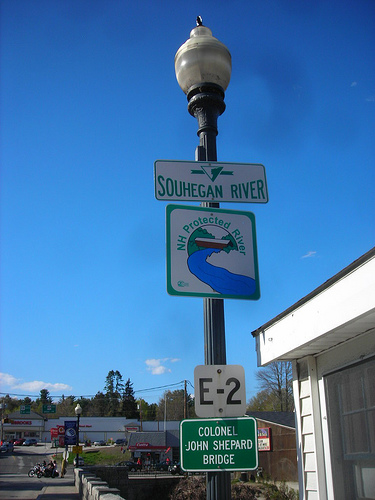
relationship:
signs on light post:
[151, 154, 270, 301] [170, 12, 236, 498]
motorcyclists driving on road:
[27, 460, 59, 478] [7, 452, 60, 490]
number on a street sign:
[224, 375, 243, 408] [193, 363, 246, 417]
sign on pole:
[157, 196, 295, 331] [130, 11, 333, 492]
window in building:
[333, 378, 364, 442] [268, 299, 362, 498]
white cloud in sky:
[296, 249, 319, 266] [51, 49, 151, 245]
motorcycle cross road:
[30, 462, 45, 477] [0, 439, 72, 499]